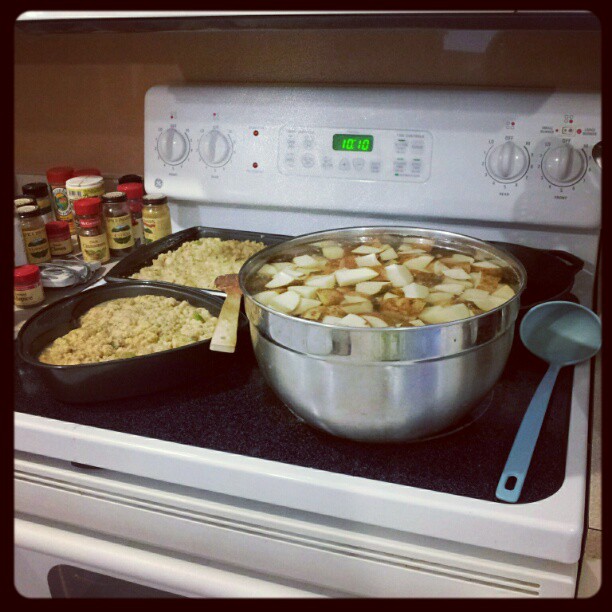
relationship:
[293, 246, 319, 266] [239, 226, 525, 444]
potato in bowl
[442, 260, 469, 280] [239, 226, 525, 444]
potato in bowl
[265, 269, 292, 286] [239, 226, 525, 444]
potato in bowl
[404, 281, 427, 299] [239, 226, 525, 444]
potato in bowl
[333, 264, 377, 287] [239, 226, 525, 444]
potato in bowl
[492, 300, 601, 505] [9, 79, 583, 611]
ladle on stove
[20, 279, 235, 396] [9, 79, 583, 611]
pan on stove